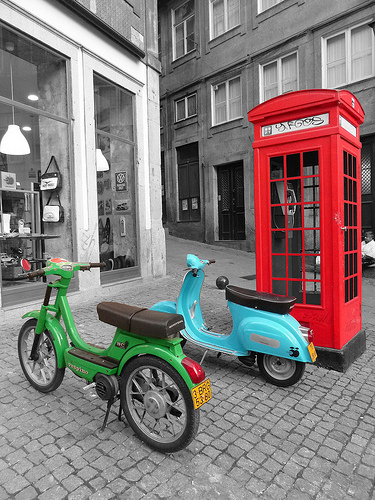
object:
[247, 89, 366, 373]
phone booth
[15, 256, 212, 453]
scooter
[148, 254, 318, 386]
scooter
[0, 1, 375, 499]
background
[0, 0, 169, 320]
store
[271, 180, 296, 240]
phone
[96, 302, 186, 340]
seat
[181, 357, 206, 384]
tail light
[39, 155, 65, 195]
handbags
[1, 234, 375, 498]
sidewalk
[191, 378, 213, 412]
license plate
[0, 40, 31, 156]
light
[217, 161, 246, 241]
door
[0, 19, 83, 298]
window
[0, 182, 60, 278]
shelf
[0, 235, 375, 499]
cobble stones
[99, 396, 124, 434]
kickstand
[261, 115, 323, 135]
graffiti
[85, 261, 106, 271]
handles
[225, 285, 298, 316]
seat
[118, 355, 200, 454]
wheel